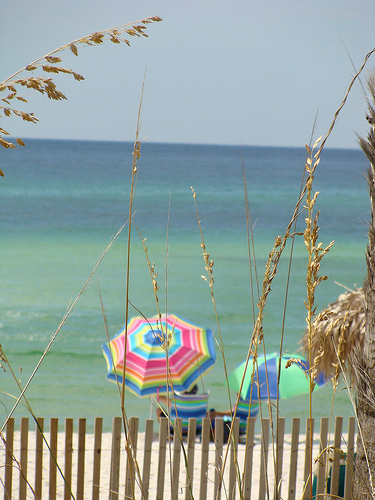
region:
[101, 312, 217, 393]
an open beach umbrellla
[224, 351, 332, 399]
an open beach umbrellla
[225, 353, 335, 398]
a blue and green striped umbrella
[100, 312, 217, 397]
a pink yellow green and blue umbrella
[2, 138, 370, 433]
a large body of water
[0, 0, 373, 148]
a hazy blue sky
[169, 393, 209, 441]
a striped beach chair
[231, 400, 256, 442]
a striped beach chair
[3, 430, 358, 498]
a brown sandy beach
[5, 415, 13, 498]
a wood fence slat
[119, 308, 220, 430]
Person under the umbrella.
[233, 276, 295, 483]
Stems growing by the picket fence.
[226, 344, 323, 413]
Umbrella on the beach.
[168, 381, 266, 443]
People sitting in beach chairs.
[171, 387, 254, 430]
The chairs has stripes.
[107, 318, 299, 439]
People relaxing on the ocean.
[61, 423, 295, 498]
The fence is wooden.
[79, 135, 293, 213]
The water is blue.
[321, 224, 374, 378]
A tree by the gate.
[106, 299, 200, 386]
The umbrella is colorful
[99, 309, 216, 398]
A rainbow striped beach umbrella.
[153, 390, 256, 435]
Two striped beach chairs.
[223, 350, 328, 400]
A green and blue beach umbrella.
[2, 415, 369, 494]
A thin wooden plank fence.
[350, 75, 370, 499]
The trunk of a palm tree.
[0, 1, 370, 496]
Sea oats along the fence.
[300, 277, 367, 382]
A dry brown palm leaf.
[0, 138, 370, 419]
Blue and green water.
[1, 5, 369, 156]
Blue skies above the water.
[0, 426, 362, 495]
Brown sand on the beach.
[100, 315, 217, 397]
An umbrella in the photo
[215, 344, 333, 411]
A blue and green umbrella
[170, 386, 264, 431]
People resting at the beach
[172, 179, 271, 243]
Ocean waters in the photo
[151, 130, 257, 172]
Water in the background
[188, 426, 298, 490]
A fence in the photo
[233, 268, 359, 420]
Dry plants in the photo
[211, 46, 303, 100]
Clouds in the photo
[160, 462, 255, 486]
Beach in the photo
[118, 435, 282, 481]
Sand in the photo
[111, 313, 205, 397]
open multi colored umbrella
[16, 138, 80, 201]
white clouds in blue sky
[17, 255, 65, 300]
white clouds in blue sky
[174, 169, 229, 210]
white clouds in blue sky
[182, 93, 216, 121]
white clouds in blue sky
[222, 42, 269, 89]
white clouds in blue sky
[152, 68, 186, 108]
white clouds in blue sky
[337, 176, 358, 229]
white clouds in blue sky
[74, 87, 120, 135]
white clouds in blue sky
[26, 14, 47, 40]
white clouds in blue sky